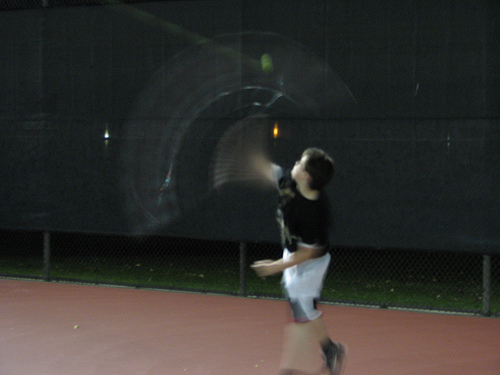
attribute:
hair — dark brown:
[302, 144, 332, 190]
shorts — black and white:
[278, 252, 336, 318]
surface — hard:
[0, 275, 498, 373]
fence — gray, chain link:
[5, 221, 497, 312]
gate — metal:
[348, 73, 485, 312]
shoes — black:
[315, 340, 362, 372]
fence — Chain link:
[45, 203, 247, 303]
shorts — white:
[250, 236, 345, 338]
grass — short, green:
[53, 247, 235, 287]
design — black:
[300, 290, 335, 320]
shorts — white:
[226, 230, 373, 346]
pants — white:
[259, 225, 344, 319]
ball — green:
[257, 49, 276, 76]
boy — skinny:
[208, 108, 377, 365]